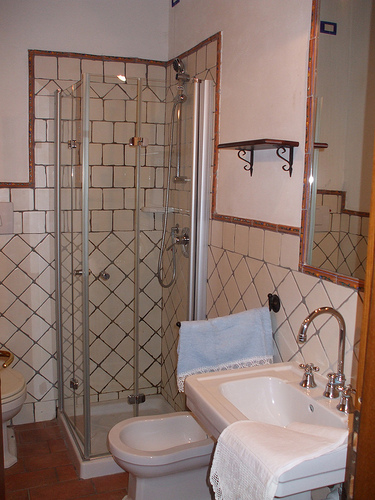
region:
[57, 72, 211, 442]
shower in the bathroom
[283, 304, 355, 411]
silver faucet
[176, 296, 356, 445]
white sink in a bathroom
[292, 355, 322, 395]
silver handle on sink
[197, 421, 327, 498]
white towel on side of sink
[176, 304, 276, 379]
white towel on rak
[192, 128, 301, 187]
small black shelf in bathroom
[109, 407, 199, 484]
white bidet in bathroom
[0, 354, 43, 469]
white toilette bowl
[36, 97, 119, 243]
white square tile on wall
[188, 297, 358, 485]
white sink with silver fixtures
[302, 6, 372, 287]
mirror above white sink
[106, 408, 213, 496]
white bidet beside sink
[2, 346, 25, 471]
white toilet bowl on left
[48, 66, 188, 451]
shower stall with glass doors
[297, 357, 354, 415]
silver knobs on sink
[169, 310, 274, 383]
towel hanging on towel rack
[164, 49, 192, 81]
silver showerhead in glass shower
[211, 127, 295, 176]
shelf above the bidet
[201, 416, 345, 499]
white towel on sink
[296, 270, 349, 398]
a metal sink faucet.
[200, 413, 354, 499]
a white towel on a sink.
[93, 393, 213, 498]
a white toilet.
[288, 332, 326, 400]
a metal faucet on a sink.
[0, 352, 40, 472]
a white toilet in a bathroom.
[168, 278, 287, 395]
a blue towel in a bathroom.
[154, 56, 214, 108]
a shower head.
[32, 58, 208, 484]
a walk in shower.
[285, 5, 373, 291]
a mirror on a bathroom wall.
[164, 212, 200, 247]
a water control for a shower.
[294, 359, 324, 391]
bathroom sink faucet control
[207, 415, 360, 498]
white hand towel with lace trim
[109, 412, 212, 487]
white toilet bowl without lid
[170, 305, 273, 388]
light blue towel with white lace edge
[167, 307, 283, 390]
light blue bathroom towel hanging from towel bar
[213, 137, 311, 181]
empty wall shelf with wrought iron supports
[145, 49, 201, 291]
adjustable bathroom shower head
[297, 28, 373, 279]
part of bathroom mirror hanging over sink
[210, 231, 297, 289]
off white ceramic bathroom wall tiles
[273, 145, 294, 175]
wrought iron S shaped shelf support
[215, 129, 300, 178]
a brown wall shelf.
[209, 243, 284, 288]
a white tile wall.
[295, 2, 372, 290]
a big brown mirror.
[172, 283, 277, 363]
a black rack with a blue and white towel.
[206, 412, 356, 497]
a white towel on the sink.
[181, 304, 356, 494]
a clean white sink.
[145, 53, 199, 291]
a grey metal shower hose.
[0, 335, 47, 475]
a white and gold knob toilet.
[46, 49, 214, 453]
a small shower.